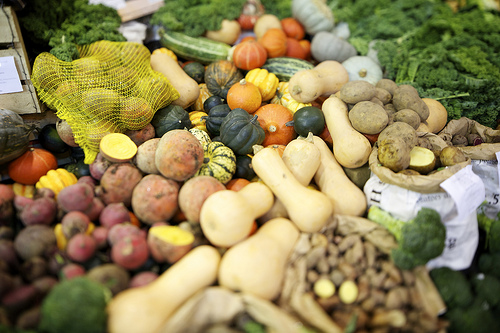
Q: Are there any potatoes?
A: Yes, there are potatoes.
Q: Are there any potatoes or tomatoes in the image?
A: Yes, there are potatoes.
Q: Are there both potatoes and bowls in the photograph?
A: No, there are potatoes but no bowls.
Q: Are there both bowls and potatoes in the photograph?
A: No, there are potatoes but no bowls.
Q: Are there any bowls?
A: No, there are no bowls.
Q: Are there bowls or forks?
A: No, there are no bowls or forks.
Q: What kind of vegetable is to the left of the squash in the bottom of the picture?
A: The vegetables are potatoes.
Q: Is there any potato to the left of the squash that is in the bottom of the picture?
A: Yes, there are potatoes to the left of the squash.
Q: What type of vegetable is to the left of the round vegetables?
A: The vegetables are potatoes.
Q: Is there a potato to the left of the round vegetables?
A: Yes, there are potatoes to the left of the vegetables.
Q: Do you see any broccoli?
A: Yes, there is broccoli.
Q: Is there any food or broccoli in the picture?
A: Yes, there is broccoli.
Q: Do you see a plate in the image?
A: No, there are no plates.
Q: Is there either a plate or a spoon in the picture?
A: No, there are no plates or spoons.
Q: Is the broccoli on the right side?
A: Yes, the broccoli is on the right of the image.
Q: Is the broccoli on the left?
A: No, the broccoli is on the right of the image.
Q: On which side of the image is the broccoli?
A: The broccoli is on the right of the image.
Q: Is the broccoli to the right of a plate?
A: No, the broccoli is to the right of a squash.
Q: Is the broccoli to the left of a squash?
A: No, the broccoli is to the right of a squash.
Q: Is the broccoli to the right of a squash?
A: Yes, the broccoli is to the right of a squash.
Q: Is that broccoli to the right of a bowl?
A: No, the broccoli is to the right of a squash.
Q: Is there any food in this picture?
A: Yes, there is food.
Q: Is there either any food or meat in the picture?
A: Yes, there is food.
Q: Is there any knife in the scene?
A: No, there are no knives.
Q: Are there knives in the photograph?
A: No, there are no knives.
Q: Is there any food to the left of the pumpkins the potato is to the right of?
A: Yes, there is food to the left of the pumpkins.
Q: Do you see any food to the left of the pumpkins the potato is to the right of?
A: Yes, there is food to the left of the pumpkins.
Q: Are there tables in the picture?
A: Yes, there is a table.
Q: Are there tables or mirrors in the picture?
A: Yes, there is a table.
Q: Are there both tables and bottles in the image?
A: No, there is a table but no bottles.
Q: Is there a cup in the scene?
A: No, there are no cups.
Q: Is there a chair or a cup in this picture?
A: No, there are no cups or chairs.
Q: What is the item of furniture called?
A: The piece of furniture is a table.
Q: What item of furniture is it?
A: The piece of furniture is a table.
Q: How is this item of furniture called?
A: This is a table.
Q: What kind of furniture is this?
A: This is a table.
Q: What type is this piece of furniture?
A: This is a table.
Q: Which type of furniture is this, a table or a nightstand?
A: This is a table.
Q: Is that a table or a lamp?
A: That is a table.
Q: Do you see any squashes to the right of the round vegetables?
A: Yes, there is a squash to the right of the veggies.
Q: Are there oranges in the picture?
A: Yes, there are oranges.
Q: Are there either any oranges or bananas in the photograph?
A: Yes, there are oranges.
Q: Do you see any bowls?
A: No, there are no bowls.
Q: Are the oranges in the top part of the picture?
A: Yes, the oranges are in the top of the image.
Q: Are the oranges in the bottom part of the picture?
A: No, the oranges are in the top of the image.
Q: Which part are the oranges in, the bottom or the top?
A: The oranges are in the top of the image.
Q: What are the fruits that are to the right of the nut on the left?
A: The fruits are oranges.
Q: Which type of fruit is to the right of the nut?
A: The fruits are oranges.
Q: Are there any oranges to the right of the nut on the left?
A: Yes, there are oranges to the right of the nut.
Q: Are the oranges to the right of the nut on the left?
A: Yes, the oranges are to the right of the nut.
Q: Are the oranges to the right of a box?
A: No, the oranges are to the right of the nut.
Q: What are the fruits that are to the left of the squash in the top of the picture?
A: The fruits are oranges.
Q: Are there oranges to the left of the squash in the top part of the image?
A: Yes, there are oranges to the left of the squash.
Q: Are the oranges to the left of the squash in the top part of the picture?
A: Yes, the oranges are to the left of the squash.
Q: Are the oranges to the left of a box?
A: No, the oranges are to the left of the squash.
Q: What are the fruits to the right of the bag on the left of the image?
A: The fruits are oranges.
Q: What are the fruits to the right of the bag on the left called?
A: The fruits are oranges.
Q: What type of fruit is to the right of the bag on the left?
A: The fruits are oranges.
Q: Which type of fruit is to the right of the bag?
A: The fruits are oranges.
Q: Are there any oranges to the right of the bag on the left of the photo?
A: Yes, there are oranges to the right of the bag.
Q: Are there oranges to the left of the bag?
A: No, the oranges are to the right of the bag.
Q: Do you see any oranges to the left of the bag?
A: No, the oranges are to the right of the bag.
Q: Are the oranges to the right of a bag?
A: Yes, the oranges are to the right of a bag.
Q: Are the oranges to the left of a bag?
A: No, the oranges are to the right of a bag.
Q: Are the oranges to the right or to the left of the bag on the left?
A: The oranges are to the right of the bag.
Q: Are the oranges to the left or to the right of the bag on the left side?
A: The oranges are to the right of the bag.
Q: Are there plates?
A: No, there are no plates.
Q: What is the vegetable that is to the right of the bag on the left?
A: The vegetable is a squash.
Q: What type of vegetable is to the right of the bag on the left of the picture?
A: The vegetable is a squash.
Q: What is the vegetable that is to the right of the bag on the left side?
A: The vegetable is a squash.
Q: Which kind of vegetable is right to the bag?
A: The vegetable is a squash.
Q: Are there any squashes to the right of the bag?
A: Yes, there is a squash to the right of the bag.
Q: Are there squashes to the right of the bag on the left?
A: Yes, there is a squash to the right of the bag.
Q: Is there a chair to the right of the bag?
A: No, there is a squash to the right of the bag.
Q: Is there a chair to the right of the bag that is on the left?
A: No, there is a squash to the right of the bag.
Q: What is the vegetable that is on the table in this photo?
A: The vegetable is a squash.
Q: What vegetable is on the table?
A: The vegetable is a squash.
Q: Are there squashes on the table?
A: Yes, there is a squash on the table.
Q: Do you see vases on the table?
A: No, there is a squash on the table.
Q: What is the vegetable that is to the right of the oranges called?
A: The vegetable is a squash.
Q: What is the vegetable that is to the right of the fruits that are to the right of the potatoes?
A: The vegetable is a squash.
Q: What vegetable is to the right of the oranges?
A: The vegetable is a squash.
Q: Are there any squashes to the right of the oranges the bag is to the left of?
A: Yes, there is a squash to the right of the oranges.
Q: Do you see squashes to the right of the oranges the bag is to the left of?
A: Yes, there is a squash to the right of the oranges.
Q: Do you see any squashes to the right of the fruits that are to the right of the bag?
A: Yes, there is a squash to the right of the oranges.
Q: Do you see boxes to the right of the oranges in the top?
A: No, there is a squash to the right of the oranges.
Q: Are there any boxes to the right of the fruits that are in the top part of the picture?
A: No, there is a squash to the right of the oranges.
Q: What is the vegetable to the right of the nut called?
A: The vegetable is a squash.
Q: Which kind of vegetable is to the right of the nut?
A: The vegetable is a squash.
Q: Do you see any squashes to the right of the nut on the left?
A: Yes, there is a squash to the right of the nut.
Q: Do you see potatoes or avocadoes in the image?
A: Yes, there is a potato.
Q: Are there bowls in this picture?
A: No, there are no bowls.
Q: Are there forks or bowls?
A: No, there are no bowls or forks.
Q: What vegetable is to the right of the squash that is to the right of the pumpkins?
A: The vegetable is a potato.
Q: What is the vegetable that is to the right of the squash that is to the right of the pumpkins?
A: The vegetable is a potato.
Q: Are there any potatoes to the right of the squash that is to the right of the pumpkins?
A: Yes, there is a potato to the right of the squash.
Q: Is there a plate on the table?
A: No, there is a potato on the table.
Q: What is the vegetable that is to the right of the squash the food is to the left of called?
A: The vegetable is a potato.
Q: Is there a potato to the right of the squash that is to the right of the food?
A: Yes, there is a potato to the right of the squash.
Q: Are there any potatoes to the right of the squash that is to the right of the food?
A: Yes, there is a potato to the right of the squash.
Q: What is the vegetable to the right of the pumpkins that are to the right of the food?
A: The vegetable is a potato.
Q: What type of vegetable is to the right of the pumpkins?
A: The vegetable is a potato.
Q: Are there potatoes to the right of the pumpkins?
A: Yes, there is a potato to the right of the pumpkins.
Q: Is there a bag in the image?
A: Yes, there is a bag.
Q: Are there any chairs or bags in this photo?
A: Yes, there is a bag.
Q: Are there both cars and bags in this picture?
A: No, there is a bag but no cars.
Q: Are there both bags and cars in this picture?
A: No, there is a bag but no cars.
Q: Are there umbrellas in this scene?
A: No, there are no umbrellas.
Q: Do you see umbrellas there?
A: No, there are no umbrellas.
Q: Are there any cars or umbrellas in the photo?
A: No, there are no umbrellas or cars.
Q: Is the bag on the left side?
A: Yes, the bag is on the left of the image.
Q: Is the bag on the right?
A: No, the bag is on the left of the image.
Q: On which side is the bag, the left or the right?
A: The bag is on the left of the image.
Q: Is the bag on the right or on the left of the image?
A: The bag is on the left of the image.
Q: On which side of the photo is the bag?
A: The bag is on the left of the image.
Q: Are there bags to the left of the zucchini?
A: Yes, there is a bag to the left of the zucchini.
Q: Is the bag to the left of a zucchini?
A: Yes, the bag is to the left of a zucchini.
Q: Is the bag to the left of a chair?
A: No, the bag is to the left of a zucchini.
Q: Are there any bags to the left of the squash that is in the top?
A: Yes, there is a bag to the left of the squash.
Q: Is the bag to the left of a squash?
A: Yes, the bag is to the left of a squash.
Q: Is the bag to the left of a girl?
A: No, the bag is to the left of a squash.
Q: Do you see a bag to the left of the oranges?
A: Yes, there is a bag to the left of the oranges.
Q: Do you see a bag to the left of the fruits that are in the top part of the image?
A: Yes, there is a bag to the left of the oranges.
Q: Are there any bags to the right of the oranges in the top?
A: No, the bag is to the left of the oranges.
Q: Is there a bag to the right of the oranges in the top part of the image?
A: No, the bag is to the left of the oranges.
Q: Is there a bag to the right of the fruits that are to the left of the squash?
A: No, the bag is to the left of the oranges.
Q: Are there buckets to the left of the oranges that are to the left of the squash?
A: No, there is a bag to the left of the oranges.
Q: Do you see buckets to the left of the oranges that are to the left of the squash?
A: No, there is a bag to the left of the oranges.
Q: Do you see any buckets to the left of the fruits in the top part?
A: No, there is a bag to the left of the oranges.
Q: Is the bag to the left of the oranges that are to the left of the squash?
A: Yes, the bag is to the left of the oranges.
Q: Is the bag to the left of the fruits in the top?
A: Yes, the bag is to the left of the oranges.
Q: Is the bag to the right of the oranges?
A: No, the bag is to the left of the oranges.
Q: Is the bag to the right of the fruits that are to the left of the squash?
A: No, the bag is to the left of the oranges.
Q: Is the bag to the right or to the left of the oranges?
A: The bag is to the left of the oranges.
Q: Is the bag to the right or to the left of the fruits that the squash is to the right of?
A: The bag is to the left of the oranges.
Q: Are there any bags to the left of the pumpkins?
A: Yes, there is a bag to the left of the pumpkins.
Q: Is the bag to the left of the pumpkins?
A: Yes, the bag is to the left of the pumpkins.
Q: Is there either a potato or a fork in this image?
A: Yes, there is a potato.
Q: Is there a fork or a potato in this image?
A: Yes, there is a potato.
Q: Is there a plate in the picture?
A: No, there are no plates.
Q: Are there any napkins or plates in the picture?
A: No, there are no plates or napkins.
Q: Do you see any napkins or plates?
A: No, there are no plates or napkins.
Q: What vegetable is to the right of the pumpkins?
A: The vegetable is a potato.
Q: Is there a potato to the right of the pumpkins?
A: Yes, there is a potato to the right of the pumpkins.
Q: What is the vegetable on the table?
A: The vegetable is a potato.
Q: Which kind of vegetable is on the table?
A: The vegetable is a potato.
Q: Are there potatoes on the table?
A: Yes, there is a potato on the table.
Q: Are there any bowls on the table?
A: No, there is a potato on the table.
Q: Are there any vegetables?
A: Yes, there are vegetables.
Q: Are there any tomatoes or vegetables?
A: Yes, there are vegetables.